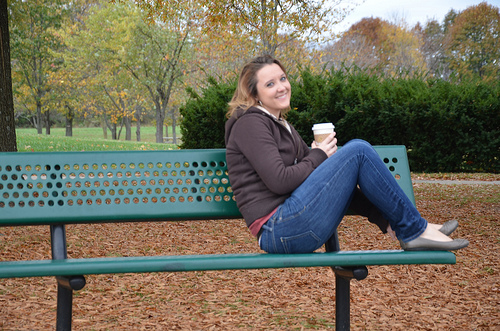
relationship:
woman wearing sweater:
[211, 46, 478, 255] [218, 95, 330, 239]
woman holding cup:
[211, 46, 478, 255] [309, 118, 338, 154]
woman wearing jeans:
[211, 46, 478, 255] [259, 135, 429, 255]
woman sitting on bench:
[211, 46, 478, 255] [2, 143, 461, 283]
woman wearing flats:
[211, 46, 478, 255] [395, 219, 470, 255]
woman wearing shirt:
[211, 46, 478, 255] [246, 208, 278, 237]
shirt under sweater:
[246, 208, 278, 237] [218, 95, 330, 239]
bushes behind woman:
[177, 64, 494, 177] [211, 46, 478, 255]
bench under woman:
[2, 143, 461, 283] [211, 46, 478, 255]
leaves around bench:
[107, 277, 320, 329] [2, 143, 461, 283]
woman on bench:
[211, 46, 478, 255] [2, 143, 461, 283]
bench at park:
[2, 143, 461, 283] [1, 126, 499, 331]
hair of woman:
[224, 60, 266, 116] [211, 46, 478, 255]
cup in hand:
[309, 118, 338, 154] [310, 131, 340, 161]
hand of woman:
[310, 131, 340, 161] [211, 46, 478, 255]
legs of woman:
[262, 133, 425, 251] [211, 46, 478, 255]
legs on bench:
[262, 133, 425, 251] [2, 143, 461, 283]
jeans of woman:
[259, 135, 429, 255] [211, 46, 478, 255]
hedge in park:
[182, 76, 499, 174] [1, 126, 499, 331]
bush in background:
[177, 64, 494, 177] [16, 117, 497, 126]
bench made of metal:
[2, 143, 461, 283] [57, 226, 62, 233]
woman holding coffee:
[211, 46, 478, 255] [309, 118, 338, 154]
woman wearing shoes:
[211, 46, 478, 255] [395, 219, 470, 255]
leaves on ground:
[107, 277, 320, 329] [0, 175, 499, 331]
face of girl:
[261, 71, 296, 107] [211, 46, 478, 255]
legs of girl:
[262, 133, 425, 251] [211, 46, 478, 255]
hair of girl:
[224, 60, 266, 116] [211, 46, 478, 255]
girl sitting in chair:
[211, 46, 478, 255] [2, 143, 461, 283]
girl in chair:
[211, 46, 478, 255] [2, 143, 461, 283]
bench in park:
[2, 143, 461, 283] [1, 126, 499, 331]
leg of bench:
[332, 266, 374, 330] [2, 143, 461, 283]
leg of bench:
[51, 277, 86, 330] [2, 143, 461, 283]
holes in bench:
[84, 166, 191, 204] [2, 143, 461, 283]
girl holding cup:
[211, 46, 478, 255] [309, 118, 338, 154]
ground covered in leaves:
[0, 175, 499, 331] [107, 277, 320, 329]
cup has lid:
[309, 118, 338, 154] [311, 122, 336, 132]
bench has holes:
[2, 143, 461, 283] [84, 166, 191, 204]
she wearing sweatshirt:
[211, 46, 478, 255] [218, 95, 330, 239]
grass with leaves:
[10, 126, 181, 157] [132, 143, 155, 152]